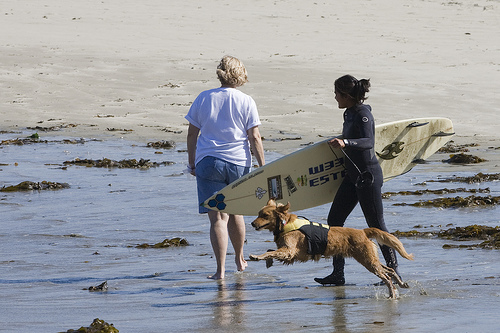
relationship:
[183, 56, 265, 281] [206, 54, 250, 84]
lady has blonde hair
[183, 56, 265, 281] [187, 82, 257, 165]
lady wearing shirt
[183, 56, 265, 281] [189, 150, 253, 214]
lady wearing shorts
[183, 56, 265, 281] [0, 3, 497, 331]
lady walking on beach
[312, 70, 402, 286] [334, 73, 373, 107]
lady has hair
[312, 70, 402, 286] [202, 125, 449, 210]
lady carrying surfboard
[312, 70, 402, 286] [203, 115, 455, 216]
lady carrying surfboard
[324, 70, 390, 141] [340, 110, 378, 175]
lady wearing wetsuit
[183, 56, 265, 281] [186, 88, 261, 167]
lady wearing shirt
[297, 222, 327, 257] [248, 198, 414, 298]
jacket on dog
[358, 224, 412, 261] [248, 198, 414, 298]
bushy tail on dog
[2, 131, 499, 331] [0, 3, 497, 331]
water on beach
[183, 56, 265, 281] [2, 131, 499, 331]
lady in water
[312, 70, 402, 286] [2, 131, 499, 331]
lady in water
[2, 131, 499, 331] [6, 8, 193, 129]
water at beach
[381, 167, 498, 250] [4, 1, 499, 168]
seaweed laying on sand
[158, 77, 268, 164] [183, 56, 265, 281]
t shirt on lady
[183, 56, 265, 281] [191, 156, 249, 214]
lady wearing denim shorts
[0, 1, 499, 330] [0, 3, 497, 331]
sand on beach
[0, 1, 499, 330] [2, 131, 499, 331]
sand covered by water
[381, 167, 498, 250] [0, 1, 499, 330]
seaweed on sand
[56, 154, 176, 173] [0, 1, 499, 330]
seaweed on sand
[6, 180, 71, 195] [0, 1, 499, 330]
seaweed on sand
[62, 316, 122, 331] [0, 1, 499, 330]
seaweed on sand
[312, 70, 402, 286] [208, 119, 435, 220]
lady holding surfboard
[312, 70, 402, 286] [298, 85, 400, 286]
lady wearing wetsuit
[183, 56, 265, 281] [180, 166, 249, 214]
lady wearing denim shorts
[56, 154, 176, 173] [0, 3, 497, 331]
seaweed on beach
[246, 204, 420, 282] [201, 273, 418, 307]
dog running on beach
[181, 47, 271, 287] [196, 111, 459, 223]
lady in front of surfboard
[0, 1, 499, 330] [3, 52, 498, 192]
sand on beach